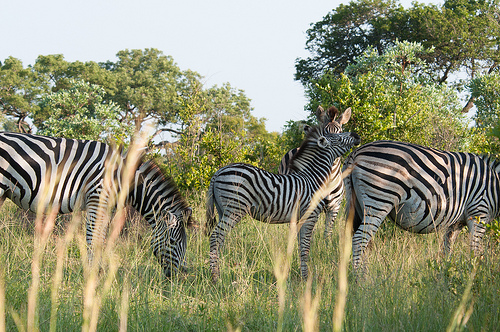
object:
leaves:
[338, 86, 358, 103]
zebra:
[340, 138, 498, 271]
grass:
[0, 197, 499, 331]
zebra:
[1, 130, 197, 283]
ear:
[315, 134, 329, 148]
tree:
[291, 0, 499, 158]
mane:
[137, 153, 198, 229]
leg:
[296, 210, 318, 278]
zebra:
[200, 104, 364, 282]